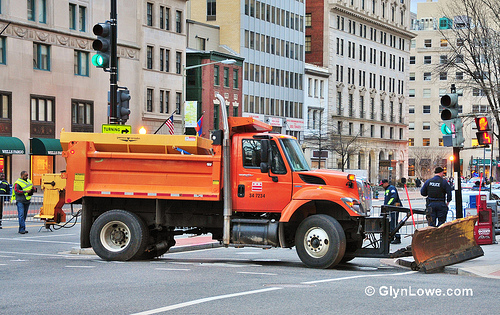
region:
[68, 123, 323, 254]
orange truck on road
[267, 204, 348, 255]
black wheels on truck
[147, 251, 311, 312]
white lines on road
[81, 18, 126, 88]
traffic light is green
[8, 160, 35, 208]
man has yellow vest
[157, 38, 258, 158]
brick face on building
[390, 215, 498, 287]
snow plow on truck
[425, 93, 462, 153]
green light on sidewalk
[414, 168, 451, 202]
man has dark blue shirt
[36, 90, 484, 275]
Orange hauling truck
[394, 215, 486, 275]
Rusted snow plowing vehicle shovel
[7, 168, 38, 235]
Person standing on a raod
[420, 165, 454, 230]
Police officer dressed in blue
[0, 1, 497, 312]
Truck accident in the city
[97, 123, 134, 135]
Neon yellow traffic sign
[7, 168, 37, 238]
Person wearing a yellow reflective vest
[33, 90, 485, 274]
Truck crashed into a curb with a snow plow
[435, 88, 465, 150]
Black traffic light fixture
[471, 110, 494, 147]
Black walking sign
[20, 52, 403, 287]
the truck is orange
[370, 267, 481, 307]
the letters are white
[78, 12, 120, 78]
the light is green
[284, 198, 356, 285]
the wheel is black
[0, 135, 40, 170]
the awning is green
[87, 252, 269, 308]
the ground is grey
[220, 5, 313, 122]
the building is grey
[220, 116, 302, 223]
the door is closed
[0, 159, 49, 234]
the man is wearing a vest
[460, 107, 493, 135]
an orange hand is showing on the traffic light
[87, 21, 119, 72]
Green traffic light illuminated.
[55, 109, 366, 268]
Orange construction truck.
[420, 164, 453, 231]
Police officer on side of road.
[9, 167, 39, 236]
Construction worker with yellow vest.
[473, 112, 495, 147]
Stop hand illuminated with 4 seconds.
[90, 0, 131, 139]
Traffic pole with two traffic lights.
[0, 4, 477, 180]
Multiple high rise buildings.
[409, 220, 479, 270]
Orange truck plow.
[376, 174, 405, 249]
Police officer on the street.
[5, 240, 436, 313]
Level street with two lanes.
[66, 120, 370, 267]
Orange construction truck on street.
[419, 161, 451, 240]
Police officer wearing police vest.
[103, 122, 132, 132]
Yellow traffic sign on light post.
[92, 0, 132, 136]
Light post with two traffic lights and a sign.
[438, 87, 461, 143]
Traffic light with green light illuminated.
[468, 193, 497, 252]
Red newspaper dispensor at intersection.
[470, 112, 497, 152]
Stop hand illuminated with 4 seconds remaining.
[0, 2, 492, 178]
Multiple downtown high rise buildings.